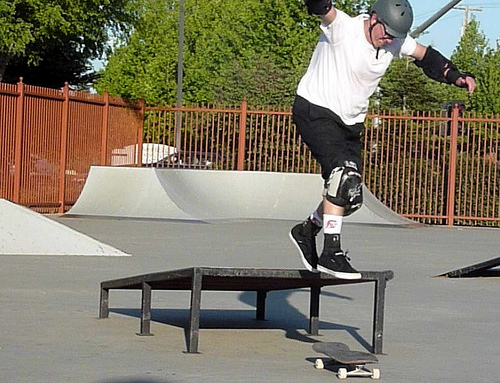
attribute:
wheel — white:
[308, 355, 327, 373]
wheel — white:
[334, 365, 350, 381]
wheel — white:
[367, 365, 383, 382]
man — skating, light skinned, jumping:
[281, 1, 479, 277]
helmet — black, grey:
[362, 0, 414, 40]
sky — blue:
[411, 0, 499, 59]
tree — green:
[1, 1, 109, 87]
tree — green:
[94, 1, 307, 180]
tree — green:
[444, 7, 494, 113]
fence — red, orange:
[0, 81, 498, 230]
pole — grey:
[172, 1, 191, 172]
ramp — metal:
[94, 263, 393, 360]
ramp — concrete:
[60, 151, 427, 230]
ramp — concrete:
[1, 190, 140, 264]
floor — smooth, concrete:
[4, 225, 499, 377]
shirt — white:
[291, 5, 417, 127]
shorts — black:
[276, 92, 378, 179]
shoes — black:
[314, 247, 363, 283]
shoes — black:
[286, 219, 321, 285]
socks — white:
[320, 211, 345, 239]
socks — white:
[306, 207, 323, 233]